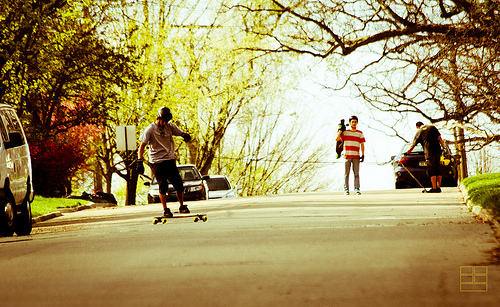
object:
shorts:
[146, 159, 184, 195]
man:
[138, 106, 192, 218]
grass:
[467, 177, 500, 207]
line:
[295, 215, 333, 219]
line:
[293, 224, 451, 229]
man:
[403, 121, 445, 193]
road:
[67, 255, 399, 304]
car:
[206, 175, 242, 200]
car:
[144, 164, 210, 204]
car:
[391, 150, 461, 190]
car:
[0, 103, 35, 238]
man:
[336, 115, 366, 196]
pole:
[125, 127, 129, 157]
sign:
[116, 126, 136, 150]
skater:
[139, 123, 184, 165]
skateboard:
[152, 213, 208, 225]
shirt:
[339, 130, 366, 159]